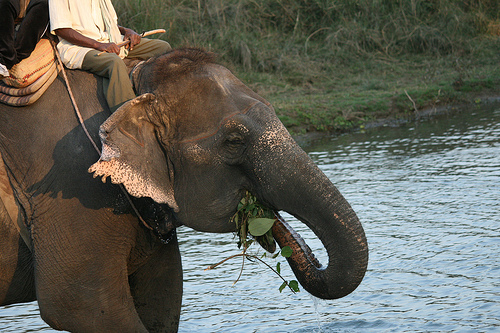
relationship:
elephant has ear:
[0, 59, 387, 329] [88, 87, 177, 206]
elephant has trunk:
[0, 59, 387, 329] [265, 133, 378, 301]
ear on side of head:
[88, 87, 177, 206] [139, 55, 376, 305]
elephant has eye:
[0, 59, 387, 329] [223, 130, 247, 150]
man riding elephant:
[44, 0, 176, 113] [0, 59, 387, 329]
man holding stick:
[44, 0, 176, 113] [99, 30, 169, 57]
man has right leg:
[44, 0, 176, 113] [75, 45, 141, 115]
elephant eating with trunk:
[0, 59, 387, 329] [265, 133, 378, 301]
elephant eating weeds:
[0, 59, 387, 329] [238, 196, 313, 290]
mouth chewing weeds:
[234, 187, 299, 253] [238, 196, 313, 290]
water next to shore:
[0, 105, 496, 332] [232, 8, 490, 135]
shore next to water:
[232, 8, 490, 135] [0, 105, 496, 332]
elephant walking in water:
[0, 59, 387, 329] [0, 105, 496, 332]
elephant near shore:
[0, 59, 387, 329] [232, 8, 490, 135]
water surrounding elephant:
[0, 105, 496, 332] [0, 59, 387, 329]